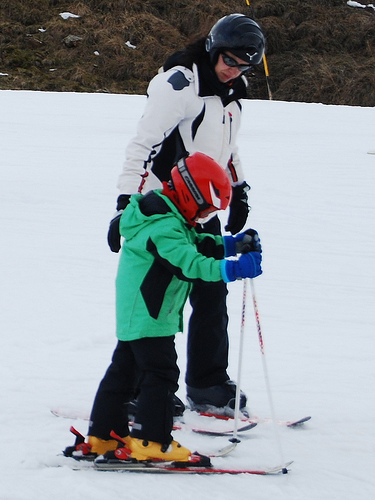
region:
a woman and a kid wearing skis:
[71, 8, 305, 481]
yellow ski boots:
[76, 429, 216, 472]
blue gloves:
[217, 227, 265, 280]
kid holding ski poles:
[225, 229, 291, 471]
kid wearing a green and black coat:
[120, 193, 211, 329]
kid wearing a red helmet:
[166, 143, 230, 228]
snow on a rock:
[52, 2, 87, 27]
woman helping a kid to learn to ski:
[88, 9, 280, 483]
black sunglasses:
[202, 52, 262, 76]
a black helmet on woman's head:
[201, 10, 266, 66]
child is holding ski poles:
[93, 231, 320, 494]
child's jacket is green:
[116, 190, 233, 369]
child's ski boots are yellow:
[88, 426, 206, 472]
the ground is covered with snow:
[18, 159, 97, 404]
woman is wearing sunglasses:
[212, 36, 286, 98]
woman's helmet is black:
[207, 13, 273, 58]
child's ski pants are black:
[77, 328, 194, 448]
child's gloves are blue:
[223, 223, 271, 300]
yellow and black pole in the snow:
[238, 0, 291, 99]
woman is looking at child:
[201, 38, 244, 247]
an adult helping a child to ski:
[61, 6, 330, 480]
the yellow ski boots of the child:
[79, 428, 201, 467]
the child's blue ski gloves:
[222, 227, 267, 282]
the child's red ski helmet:
[167, 151, 233, 225]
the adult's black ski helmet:
[209, 17, 269, 67]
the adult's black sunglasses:
[221, 51, 251, 82]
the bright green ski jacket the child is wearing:
[117, 204, 202, 339]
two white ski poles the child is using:
[231, 272, 294, 477]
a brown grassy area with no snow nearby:
[6, 23, 141, 90]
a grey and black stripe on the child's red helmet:
[172, 160, 209, 208]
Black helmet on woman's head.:
[197, 12, 277, 63]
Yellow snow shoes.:
[114, 429, 204, 464]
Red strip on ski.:
[169, 467, 270, 475]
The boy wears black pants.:
[86, 330, 185, 448]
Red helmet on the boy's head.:
[168, 144, 237, 218]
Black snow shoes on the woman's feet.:
[185, 371, 253, 416]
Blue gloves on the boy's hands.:
[223, 228, 273, 285]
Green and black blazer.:
[119, 190, 204, 341]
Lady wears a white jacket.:
[119, 94, 235, 151]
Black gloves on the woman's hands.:
[220, 181, 255, 238]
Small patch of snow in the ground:
[48, 171, 64, 189]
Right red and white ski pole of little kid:
[237, 298, 253, 376]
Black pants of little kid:
[105, 341, 171, 393]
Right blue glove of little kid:
[233, 256, 271, 277]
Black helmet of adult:
[228, 19, 251, 45]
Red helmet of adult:
[177, 165, 225, 195]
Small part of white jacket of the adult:
[202, 104, 218, 150]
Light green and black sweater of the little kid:
[130, 235, 179, 322]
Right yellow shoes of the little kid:
[129, 432, 164, 458]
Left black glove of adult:
[227, 195, 253, 228]